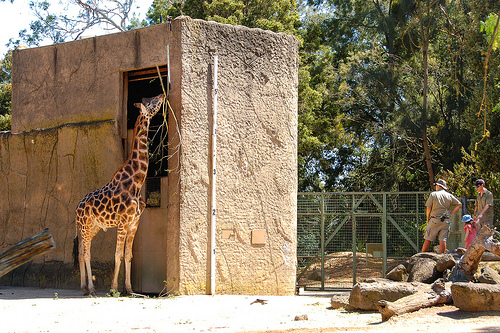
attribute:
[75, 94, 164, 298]
giraffe — eating, baby, tall, standing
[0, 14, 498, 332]
habitat — wooded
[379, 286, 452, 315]
log — fallen, wood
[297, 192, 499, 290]
fence — chain link, metal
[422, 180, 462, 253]
zoo keeper — inspecting, standing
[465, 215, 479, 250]
daughter — little, visiting, small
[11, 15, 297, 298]
buiding — small, clay, interesting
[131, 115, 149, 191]
neck — tall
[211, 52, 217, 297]
pole — tall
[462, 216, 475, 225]
hat — blue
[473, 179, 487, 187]
visor — blue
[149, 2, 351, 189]
tree — green, tall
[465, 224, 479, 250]
shirt — pink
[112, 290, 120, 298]
hooves — black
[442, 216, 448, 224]
gun — black